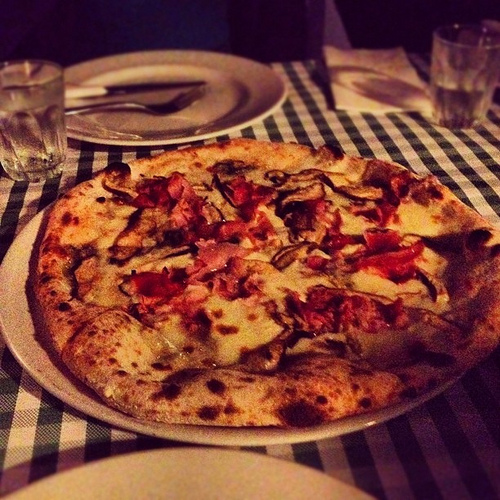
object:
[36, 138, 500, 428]
pizza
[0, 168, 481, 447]
plate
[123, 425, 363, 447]
edge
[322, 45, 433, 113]
napkin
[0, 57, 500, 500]
table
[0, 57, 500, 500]
table cloth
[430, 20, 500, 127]
glass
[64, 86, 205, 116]
fork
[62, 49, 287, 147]
plate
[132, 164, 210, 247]
toppings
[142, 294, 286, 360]
cheese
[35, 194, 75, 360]
crust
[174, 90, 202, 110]
prongs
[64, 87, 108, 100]
knife handle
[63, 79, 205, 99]
knife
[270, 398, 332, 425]
burnt spot